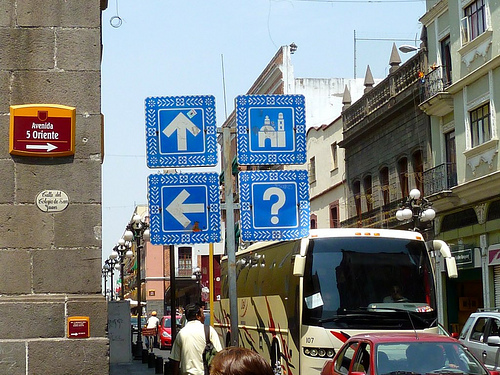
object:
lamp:
[396, 188, 436, 222]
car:
[320, 332, 500, 375]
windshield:
[375, 341, 490, 374]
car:
[456, 311, 500, 372]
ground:
[320, 67, 343, 90]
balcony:
[417, 65, 455, 117]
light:
[402, 209, 412, 220]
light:
[420, 209, 436, 222]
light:
[409, 189, 421, 200]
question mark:
[262, 187, 286, 224]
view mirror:
[445, 256, 459, 279]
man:
[168, 302, 222, 375]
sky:
[102, 0, 427, 297]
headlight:
[303, 346, 336, 358]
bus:
[211, 228, 458, 374]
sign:
[8, 103, 75, 157]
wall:
[0, 0, 110, 375]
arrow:
[162, 112, 202, 152]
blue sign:
[239, 170, 310, 242]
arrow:
[26, 142, 58, 152]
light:
[123, 231, 133, 241]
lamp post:
[134, 238, 146, 361]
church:
[258, 112, 286, 148]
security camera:
[399, 45, 417, 53]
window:
[469, 101, 492, 148]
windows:
[220, 240, 302, 352]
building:
[417, 0, 499, 336]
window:
[302, 237, 439, 331]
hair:
[203, 346, 277, 374]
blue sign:
[144, 95, 218, 168]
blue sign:
[147, 172, 220, 246]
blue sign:
[235, 94, 307, 165]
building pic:
[249, 106, 296, 153]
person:
[207, 346, 273, 374]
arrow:
[166, 188, 205, 229]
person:
[418, 71, 429, 98]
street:
[106, 302, 132, 365]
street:
[121, 303, 262, 372]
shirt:
[166, 320, 222, 375]